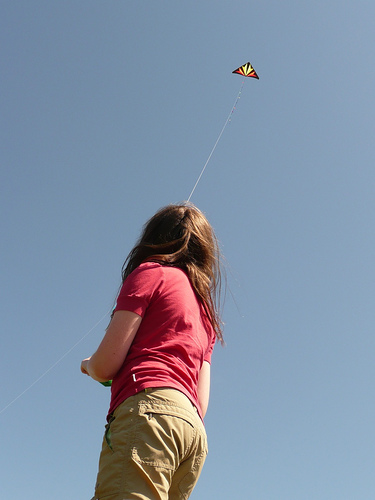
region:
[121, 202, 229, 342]
the girl has long hair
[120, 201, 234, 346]
the hair is brown in color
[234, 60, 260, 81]
the kite is in the air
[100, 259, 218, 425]
the girl is wearing a short sleeved shirt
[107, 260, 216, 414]
the shirt is red in color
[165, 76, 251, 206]
a string is attached to the kite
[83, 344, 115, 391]
the girl is holding a string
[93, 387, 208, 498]
the girl is wearing pants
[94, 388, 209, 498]
the pants are tan in color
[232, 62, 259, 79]
the kite is yellow red and black in color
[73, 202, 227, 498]
A woman flying a kite.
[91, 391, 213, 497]
a pair of brown pants on a woman.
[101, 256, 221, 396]
a red shirt on a woman.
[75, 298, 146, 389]
the left arm of a woman.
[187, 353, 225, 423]
the right arm of a woman.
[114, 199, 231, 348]
brown hair on a woman.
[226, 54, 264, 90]
a kite flying in a blue sky.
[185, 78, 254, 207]
a white kite string.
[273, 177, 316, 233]
A section of clear blue sky.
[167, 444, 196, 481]
A woman with a murph.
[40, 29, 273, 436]
The girl is flying a kite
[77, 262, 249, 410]
The girl is wearing a red shirt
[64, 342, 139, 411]
The girl is holding a green handle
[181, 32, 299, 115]
The kite is black, orange, and yellow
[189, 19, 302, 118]
The kite is triangular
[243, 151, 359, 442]
The background of the image is completely blue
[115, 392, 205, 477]
The girl's pocket closes with a zipper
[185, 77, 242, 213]
The kite is connected to a white string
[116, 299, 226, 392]
The girl's shirt is red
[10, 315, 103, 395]
The string doesn't seem to belong to the kite in the picture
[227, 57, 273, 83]
kite flying in air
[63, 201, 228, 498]
girl wearing red t-shirt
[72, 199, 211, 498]
girl wearing kaki pants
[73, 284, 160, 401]
girl holding kite string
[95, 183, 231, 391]
girl has long dark hair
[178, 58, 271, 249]
kite hanging by a string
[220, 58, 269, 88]
kite is black, yellow, and red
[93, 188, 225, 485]
girl looking up in the air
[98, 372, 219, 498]
pants with back zipper pocket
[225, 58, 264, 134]
kite with long multi colored tail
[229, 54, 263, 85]
A yellow, red and blackkite in the sky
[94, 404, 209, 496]
A person wearing khaki pants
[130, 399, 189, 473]
A back pocket with a zipper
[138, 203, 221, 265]
The back of a person's brownish/red hair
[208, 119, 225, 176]
A white string in the sky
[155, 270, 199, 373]
A person wearing a red tee shirt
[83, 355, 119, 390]
A bare left elbow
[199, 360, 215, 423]
A bare right arm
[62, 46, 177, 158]
A clear bly sky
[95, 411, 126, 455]
The side pocket of a pair of pants